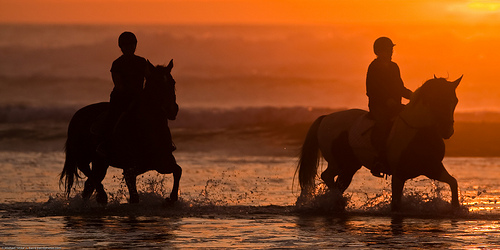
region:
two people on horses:
[75, 31, 492, 222]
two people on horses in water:
[100, 27, 495, 227]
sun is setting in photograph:
[270, 0, 494, 108]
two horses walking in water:
[60, 14, 468, 246]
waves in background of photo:
[10, 22, 475, 173]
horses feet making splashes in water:
[15, 158, 497, 248]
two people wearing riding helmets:
[97, 14, 467, 78]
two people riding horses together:
[32, 22, 494, 149]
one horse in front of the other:
[65, 20, 497, 240]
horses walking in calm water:
[64, 57, 451, 237]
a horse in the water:
[47, 20, 215, 246]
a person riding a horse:
[28, 9, 240, 249]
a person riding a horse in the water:
[47, 4, 240, 248]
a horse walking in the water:
[27, 11, 230, 244]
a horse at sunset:
[30, 17, 231, 234]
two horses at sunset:
[12, 10, 494, 186]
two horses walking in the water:
[12, 13, 479, 248]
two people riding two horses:
[14, 12, 477, 248]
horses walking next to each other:
[34, 10, 468, 232]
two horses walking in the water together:
[32, 10, 483, 249]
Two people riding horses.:
[41, 20, 492, 236]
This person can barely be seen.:
[53, 24, 210, 214]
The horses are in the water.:
[18, 127, 493, 229]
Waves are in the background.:
[10, 80, 496, 183]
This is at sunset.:
[261, 2, 490, 63]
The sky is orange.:
[174, 7, 366, 77]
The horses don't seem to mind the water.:
[48, 19, 482, 231]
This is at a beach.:
[17, 10, 492, 228]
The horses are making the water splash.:
[31, 18, 484, 230]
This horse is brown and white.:
[274, 26, 482, 234]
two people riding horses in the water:
[32, 19, 487, 230]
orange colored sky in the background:
[152, 1, 492, 38]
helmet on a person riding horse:
[359, 30, 409, 50]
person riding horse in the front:
[292, 28, 483, 230]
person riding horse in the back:
[42, 23, 212, 223]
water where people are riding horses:
[3, 210, 494, 248]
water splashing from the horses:
[189, 181, 236, 204]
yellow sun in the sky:
[452, 4, 499, 21]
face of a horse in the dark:
[426, 66, 471, 146]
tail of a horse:
[292, 111, 323, 206]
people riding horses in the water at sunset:
[27, 12, 493, 230]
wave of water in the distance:
[207, 82, 297, 154]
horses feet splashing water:
[26, 181, 486, 228]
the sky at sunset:
[14, 3, 499, 95]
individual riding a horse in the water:
[282, 27, 489, 239]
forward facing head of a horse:
[140, 60, 187, 128]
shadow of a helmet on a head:
[370, 33, 400, 55]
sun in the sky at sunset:
[447, 1, 498, 25]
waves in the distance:
[190, 6, 299, 136]